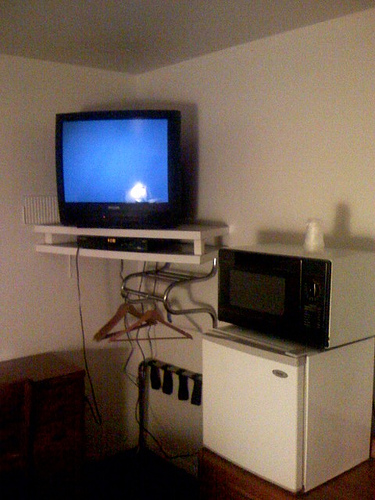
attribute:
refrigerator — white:
[190, 324, 373, 487]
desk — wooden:
[0, 347, 101, 493]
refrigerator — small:
[180, 318, 336, 496]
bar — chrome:
[118, 257, 218, 329]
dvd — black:
[82, 237, 164, 251]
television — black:
[52, 105, 190, 227]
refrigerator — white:
[180, 293, 335, 498]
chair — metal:
[112, 342, 200, 470]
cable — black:
[74, 245, 102, 422]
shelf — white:
[35, 224, 231, 264]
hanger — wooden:
[91, 286, 157, 342]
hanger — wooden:
[107, 293, 192, 342]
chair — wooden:
[23, 367, 123, 461]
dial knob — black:
[305, 280, 320, 299]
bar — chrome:
[134, 357, 196, 471]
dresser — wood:
[0, 350, 92, 475]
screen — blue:
[57, 119, 170, 203]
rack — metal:
[119, 268, 222, 336]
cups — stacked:
[299, 218, 329, 257]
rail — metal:
[119, 269, 187, 314]